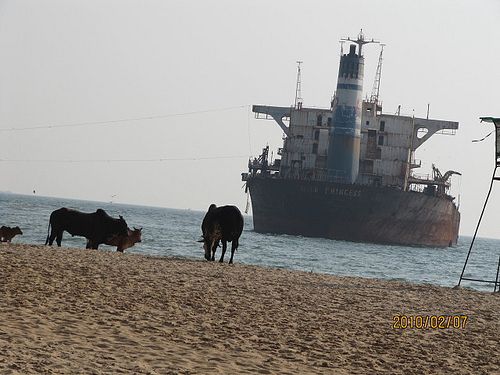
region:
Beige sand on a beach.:
[37, 304, 311, 374]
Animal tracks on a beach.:
[285, 309, 400, 372]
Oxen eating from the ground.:
[47, 205, 147, 260]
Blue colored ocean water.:
[281, 247, 498, 264]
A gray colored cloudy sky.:
[9, 0, 441, 25]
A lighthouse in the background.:
[28, 179, 43, 203]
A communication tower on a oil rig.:
[292, 50, 309, 106]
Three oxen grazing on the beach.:
[0, 197, 245, 269]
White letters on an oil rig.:
[302, 180, 384, 212]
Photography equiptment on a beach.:
[453, 112, 498, 292]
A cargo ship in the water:
[290, 110, 415, 230]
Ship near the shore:
[292, 111, 404, 233]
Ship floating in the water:
[261, 197, 425, 232]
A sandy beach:
[277, 279, 366, 339]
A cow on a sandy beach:
[202, 206, 239, 262]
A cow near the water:
[203, 206, 242, 261]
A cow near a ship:
[201, 205, 241, 262]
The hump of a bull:
[96, 207, 106, 214]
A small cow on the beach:
[1, 225, 22, 240]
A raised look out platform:
[495, 117, 499, 163]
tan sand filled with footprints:
[5, 241, 495, 367]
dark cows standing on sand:
[0, 200, 245, 266]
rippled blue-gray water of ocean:
[0, 185, 495, 290]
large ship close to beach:
[240, 26, 460, 306]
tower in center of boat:
[245, 32, 456, 252]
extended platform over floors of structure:
[250, 100, 455, 182]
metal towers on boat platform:
[286, 41, 386, 113]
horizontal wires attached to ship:
[0, 100, 265, 175]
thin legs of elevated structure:
[440, 110, 495, 285]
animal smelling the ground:
[198, 203, 243, 264]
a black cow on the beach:
[191, 196, 247, 266]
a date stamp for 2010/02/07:
[391, 310, 479, 332]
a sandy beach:
[1, 232, 498, 373]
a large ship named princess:
[238, 30, 466, 252]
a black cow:
[0, 222, 25, 243]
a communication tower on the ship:
[289, 54, 307, 111]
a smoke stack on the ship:
[326, 42, 368, 192]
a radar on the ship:
[337, 19, 389, 55]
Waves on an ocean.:
[296, 246, 413, 267]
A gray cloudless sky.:
[13, 9, 243, 124]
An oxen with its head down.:
[199, 200, 244, 264]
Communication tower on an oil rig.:
[366, 35, 385, 118]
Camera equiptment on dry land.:
[457, 115, 499, 297]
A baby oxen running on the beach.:
[1, 219, 25, 246]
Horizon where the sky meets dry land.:
[4, 188, 494, 249]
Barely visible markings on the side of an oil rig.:
[299, 182, 373, 202]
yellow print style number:
[390, 313, 402, 333]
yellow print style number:
[413, 313, 424, 329]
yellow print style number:
[429, 313, 436, 329]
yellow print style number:
[436, 313, 449, 329]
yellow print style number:
[452, 313, 462, 330]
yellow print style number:
[459, 312, 466, 329]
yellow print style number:
[391, 314, 424, 331]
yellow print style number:
[430, 315, 447, 334]